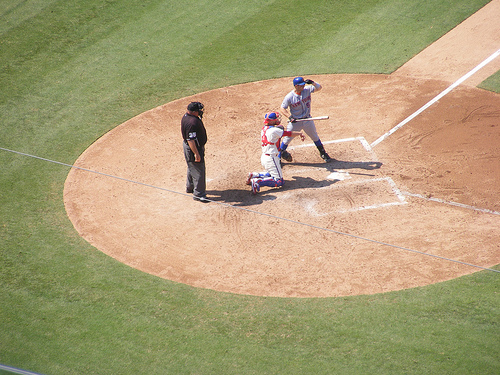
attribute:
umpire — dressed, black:
[177, 100, 214, 206]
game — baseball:
[2, 2, 499, 343]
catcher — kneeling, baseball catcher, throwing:
[245, 109, 308, 201]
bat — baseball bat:
[286, 112, 331, 125]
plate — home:
[327, 166, 355, 183]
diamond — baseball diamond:
[263, 1, 500, 224]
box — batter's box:
[261, 93, 416, 221]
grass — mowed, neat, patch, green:
[2, 0, 500, 375]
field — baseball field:
[1, 1, 498, 365]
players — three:
[160, 48, 345, 225]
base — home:
[315, 163, 363, 188]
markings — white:
[0, 59, 499, 220]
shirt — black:
[175, 110, 211, 151]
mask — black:
[196, 102, 206, 120]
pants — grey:
[177, 141, 209, 201]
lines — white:
[370, 17, 500, 229]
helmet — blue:
[284, 75, 309, 92]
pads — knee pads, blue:
[275, 178, 285, 188]